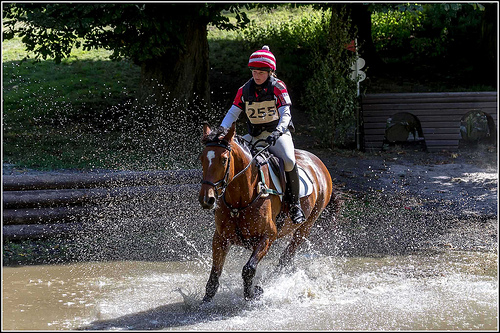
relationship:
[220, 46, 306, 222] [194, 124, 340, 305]
girl riding horse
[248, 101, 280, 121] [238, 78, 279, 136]
three-digit number on vest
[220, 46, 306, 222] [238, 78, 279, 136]
girl wearing vest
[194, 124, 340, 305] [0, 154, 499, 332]
horse splashing through water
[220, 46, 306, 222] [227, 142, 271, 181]
girl holding onto reins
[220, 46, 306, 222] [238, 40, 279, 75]
girl wearing knitted hat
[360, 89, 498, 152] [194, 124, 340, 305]
wooden barrier behind horse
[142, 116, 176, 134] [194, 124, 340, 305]
drops of water surrounding horse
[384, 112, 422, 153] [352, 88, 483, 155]
arched cutouts in wall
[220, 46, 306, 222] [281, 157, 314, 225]
girl wearing black boot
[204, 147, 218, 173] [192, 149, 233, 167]
white splotch between eyes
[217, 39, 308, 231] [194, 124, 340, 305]
girl riding horse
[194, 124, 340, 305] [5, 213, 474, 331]
horse in water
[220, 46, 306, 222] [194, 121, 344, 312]
girl riding horse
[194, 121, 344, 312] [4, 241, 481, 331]
horse through water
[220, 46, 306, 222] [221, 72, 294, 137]
girl with jersey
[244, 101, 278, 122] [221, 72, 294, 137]
225 on jersey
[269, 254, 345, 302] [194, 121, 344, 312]
splashed water from horse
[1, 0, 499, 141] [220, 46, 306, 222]
trees behind behind girl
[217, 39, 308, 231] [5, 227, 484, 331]
girl riding water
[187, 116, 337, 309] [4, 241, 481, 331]
horse in the water running through water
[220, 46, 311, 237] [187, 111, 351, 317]
girl riding horse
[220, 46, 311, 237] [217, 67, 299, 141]
girl with jersey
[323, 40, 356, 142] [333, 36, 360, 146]
tall weed by flag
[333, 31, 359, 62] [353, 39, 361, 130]
red flag on pole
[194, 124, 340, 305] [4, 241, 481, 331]
horse splashing through water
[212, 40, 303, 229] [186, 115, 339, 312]
person on horse